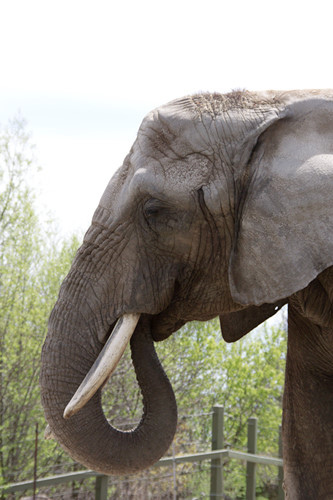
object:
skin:
[58, 211, 125, 326]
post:
[95, 405, 282, 500]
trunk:
[40, 289, 178, 478]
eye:
[144, 205, 160, 216]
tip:
[59, 409, 72, 420]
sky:
[0, 0, 330, 233]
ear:
[219, 296, 290, 343]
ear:
[226, 97, 332, 308]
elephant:
[36, 85, 333, 500]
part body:
[287, 327, 318, 446]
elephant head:
[103, 87, 305, 344]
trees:
[174, 336, 281, 435]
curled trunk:
[38, 242, 177, 476]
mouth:
[123, 279, 182, 343]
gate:
[0, 311, 288, 500]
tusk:
[60, 311, 141, 419]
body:
[39, 86, 333, 500]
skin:
[175, 233, 235, 303]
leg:
[279, 334, 333, 500]